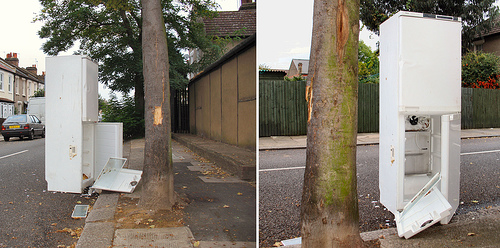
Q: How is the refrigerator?
A: Broken.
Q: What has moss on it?
A: A tree.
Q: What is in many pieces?
A: A fridge.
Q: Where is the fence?
A: On the side of the road.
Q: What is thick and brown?
A: Tree trunk.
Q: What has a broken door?
A: Fridge.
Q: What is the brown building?
A: House.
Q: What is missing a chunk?
A: Tree trunk.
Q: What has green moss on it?
A: Tree trunk.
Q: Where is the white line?
A: On pavement.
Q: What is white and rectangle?
A: The fridge.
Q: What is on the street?
A: Fridge.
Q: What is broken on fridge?
A: Bottom door.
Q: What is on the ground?
A: Fridge shelves.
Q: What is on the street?
A: White refrigerator.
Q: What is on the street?
A: Old white refrigerator.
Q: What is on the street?
A: Broken old refrigerator.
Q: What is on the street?
A: Broken white refrigerator.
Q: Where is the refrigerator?
A: On the curb.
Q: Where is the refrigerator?
A: On the curb.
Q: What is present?
A: A busted fridge.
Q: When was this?
A: Daytime.